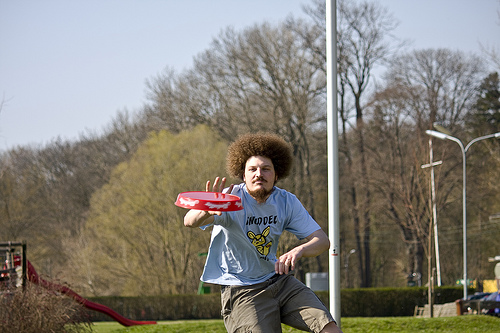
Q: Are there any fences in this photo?
A: No, there are no fences.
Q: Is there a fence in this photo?
A: No, there are no fences.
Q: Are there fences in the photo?
A: No, there are no fences.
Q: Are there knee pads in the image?
A: No, there are no knee pads.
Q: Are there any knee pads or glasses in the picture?
A: No, there are no knee pads or glasses.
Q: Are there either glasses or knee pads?
A: No, there are no knee pads or glasses.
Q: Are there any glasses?
A: No, there are no glasses.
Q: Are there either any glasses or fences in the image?
A: No, there are no glasses or fences.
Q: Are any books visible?
A: No, there are no books.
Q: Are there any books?
A: No, there are no books.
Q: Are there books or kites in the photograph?
A: No, there are no books or kites.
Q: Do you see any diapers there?
A: No, there are no diapers.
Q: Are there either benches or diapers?
A: No, there are no diapers or benches.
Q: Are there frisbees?
A: Yes, there is a frisbee.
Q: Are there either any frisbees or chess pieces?
A: Yes, there is a frisbee.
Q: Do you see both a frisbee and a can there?
A: No, there is a frisbee but no cans.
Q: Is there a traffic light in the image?
A: No, there are no traffic lights.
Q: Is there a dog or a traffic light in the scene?
A: No, there are no traffic lights or dogs.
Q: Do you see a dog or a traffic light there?
A: No, there are no traffic lights or dogs.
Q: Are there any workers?
A: No, there are no workers.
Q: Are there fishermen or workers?
A: No, there are no workers or fishermen.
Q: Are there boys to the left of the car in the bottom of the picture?
A: Yes, there is a boy to the left of the car.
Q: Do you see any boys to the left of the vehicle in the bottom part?
A: Yes, there is a boy to the left of the car.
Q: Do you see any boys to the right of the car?
A: No, the boy is to the left of the car.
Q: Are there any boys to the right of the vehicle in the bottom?
A: No, the boy is to the left of the car.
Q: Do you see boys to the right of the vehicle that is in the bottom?
A: No, the boy is to the left of the car.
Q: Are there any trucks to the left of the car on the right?
A: No, there is a boy to the left of the car.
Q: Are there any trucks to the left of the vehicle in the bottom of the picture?
A: No, there is a boy to the left of the car.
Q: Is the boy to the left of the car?
A: Yes, the boy is to the left of the car.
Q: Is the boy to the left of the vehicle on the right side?
A: Yes, the boy is to the left of the car.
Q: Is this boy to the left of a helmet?
A: No, the boy is to the left of the car.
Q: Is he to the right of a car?
A: No, the boy is to the left of a car.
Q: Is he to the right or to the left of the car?
A: The boy is to the left of the car.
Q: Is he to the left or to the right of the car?
A: The boy is to the left of the car.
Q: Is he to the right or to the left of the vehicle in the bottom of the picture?
A: The boy is to the left of the car.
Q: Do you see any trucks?
A: No, there are no trucks.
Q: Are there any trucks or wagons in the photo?
A: No, there are no trucks or wagons.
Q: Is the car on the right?
A: Yes, the car is on the right of the image.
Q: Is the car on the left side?
A: No, the car is on the right of the image.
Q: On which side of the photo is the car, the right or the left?
A: The car is on the right of the image.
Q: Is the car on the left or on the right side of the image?
A: The car is on the right of the image.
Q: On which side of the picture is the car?
A: The car is on the right of the image.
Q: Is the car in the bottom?
A: Yes, the car is in the bottom of the image.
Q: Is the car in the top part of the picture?
A: No, the car is in the bottom of the image.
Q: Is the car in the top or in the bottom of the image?
A: The car is in the bottom of the image.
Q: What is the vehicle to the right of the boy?
A: The vehicle is a car.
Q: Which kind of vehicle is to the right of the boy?
A: The vehicle is a car.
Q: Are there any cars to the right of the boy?
A: Yes, there is a car to the right of the boy.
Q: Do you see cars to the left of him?
A: No, the car is to the right of the boy.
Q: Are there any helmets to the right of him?
A: No, there is a car to the right of the boy.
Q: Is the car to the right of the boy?
A: Yes, the car is to the right of the boy.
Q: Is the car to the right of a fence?
A: No, the car is to the right of the boy.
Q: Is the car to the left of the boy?
A: No, the car is to the right of the boy.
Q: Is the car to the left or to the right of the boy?
A: The car is to the right of the boy.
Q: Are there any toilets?
A: No, there are no toilets.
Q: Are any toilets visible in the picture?
A: No, there are no toilets.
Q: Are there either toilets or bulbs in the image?
A: No, there are no toilets or bulbs.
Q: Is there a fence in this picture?
A: No, there are no fences.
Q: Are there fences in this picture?
A: No, there are no fences.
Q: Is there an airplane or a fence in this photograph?
A: No, there are no fences or airplanes.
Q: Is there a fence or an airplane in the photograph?
A: No, there are no fences or airplanes.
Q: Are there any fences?
A: No, there are no fences.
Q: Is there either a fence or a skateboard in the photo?
A: No, there are no fences or skateboards.